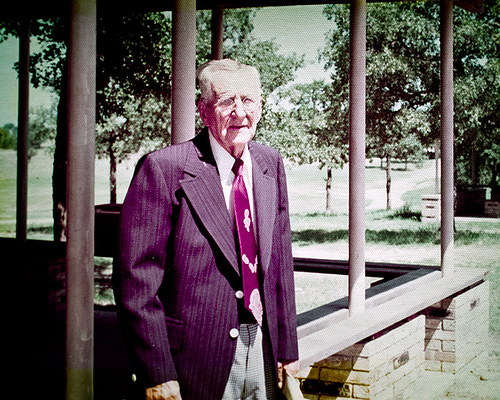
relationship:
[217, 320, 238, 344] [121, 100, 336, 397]
button on jacket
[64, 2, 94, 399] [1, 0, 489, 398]
column on gazebo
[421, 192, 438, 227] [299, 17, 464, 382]
sign in park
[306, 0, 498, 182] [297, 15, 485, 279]
trees lining park trail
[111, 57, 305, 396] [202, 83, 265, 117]
man wearing glasses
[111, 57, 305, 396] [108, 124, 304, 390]
man wearing suit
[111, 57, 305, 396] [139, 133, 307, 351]
man wearing jacket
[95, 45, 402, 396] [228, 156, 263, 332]
man wearing purple tie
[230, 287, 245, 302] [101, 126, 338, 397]
button on a jacket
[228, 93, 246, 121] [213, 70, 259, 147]
nose on a face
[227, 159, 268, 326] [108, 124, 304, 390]
tie under mans suit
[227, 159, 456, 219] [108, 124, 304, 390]
tie under mans suit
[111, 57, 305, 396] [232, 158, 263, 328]
man wearing tie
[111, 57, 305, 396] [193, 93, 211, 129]
man has ear